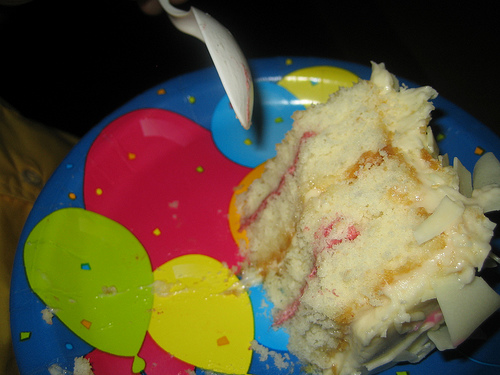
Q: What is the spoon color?
A: White.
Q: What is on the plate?
A: Cake.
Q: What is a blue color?
A: A plate.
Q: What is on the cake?
A: White frosting.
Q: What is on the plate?
A: A blue balloon.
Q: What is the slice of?
A: Cake.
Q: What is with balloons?
A: A blue plate.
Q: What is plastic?
A: A white spoon.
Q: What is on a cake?
A: White frosting.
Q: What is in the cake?
A: Pink filling.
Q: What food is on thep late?
A: Cake.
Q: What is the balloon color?
A: Green.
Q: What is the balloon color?
A: Yellow.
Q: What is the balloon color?
A: Blue.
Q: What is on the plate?
A: Cake.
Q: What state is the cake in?
A: Partially eaten.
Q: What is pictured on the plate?
A: Balloons.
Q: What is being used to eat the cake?
A: Spoon.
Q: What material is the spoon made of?
A: Plastic.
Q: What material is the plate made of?
A: Paper.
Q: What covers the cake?
A: Icing.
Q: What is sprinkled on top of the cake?
A: White chocolate shavings.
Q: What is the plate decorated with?
A: Balloons.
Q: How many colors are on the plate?
A: Five.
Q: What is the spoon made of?
A: Plastic.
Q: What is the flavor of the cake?
A: White.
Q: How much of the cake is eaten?
A: Half.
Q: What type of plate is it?
A: Birthday party plate.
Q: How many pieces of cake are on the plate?
A: One.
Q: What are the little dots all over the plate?
A: Confetti decorations.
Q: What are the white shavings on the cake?
A: White chocolate.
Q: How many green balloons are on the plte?
A: One.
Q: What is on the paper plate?
A: Birthday cake.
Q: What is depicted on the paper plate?
A: Balloons.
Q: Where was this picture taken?
A: At a party.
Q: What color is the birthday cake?
A: White.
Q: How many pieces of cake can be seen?
A: One.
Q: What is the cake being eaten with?
A: A spoon.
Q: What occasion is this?
A: A birthday party.